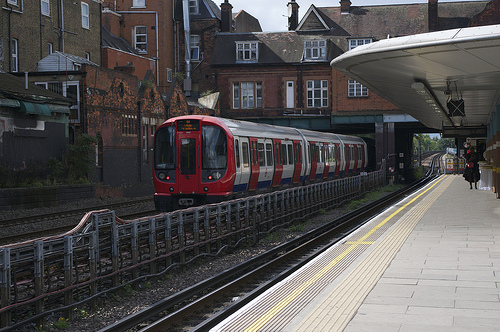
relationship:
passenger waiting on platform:
[460, 144, 480, 189] [209, 170, 499, 330]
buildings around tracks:
[3, 1, 485, 186] [18, 160, 428, 330]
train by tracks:
[141, 103, 393, 208] [217, 219, 319, 259]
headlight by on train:
[206, 172, 214, 182] [147, 109, 377, 214]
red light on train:
[207, 175, 212, 180] [147, 109, 377, 214]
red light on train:
[163, 172, 171, 181] [147, 109, 377, 214]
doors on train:
[235, 134, 370, 177] [229, 121, 354, 171]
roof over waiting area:
[326, 39, 478, 141] [370, 140, 489, 307]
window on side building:
[231, 83, 263, 106] [217, 21, 346, 137]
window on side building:
[306, 80, 328, 109] [217, 21, 346, 137]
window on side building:
[304, 40, 327, 60] [217, 21, 346, 137]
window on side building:
[305, 82, 332, 100] [211, 22, 341, 118]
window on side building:
[304, 42, 325, 59] [210, 2, 479, 125]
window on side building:
[188, 37, 203, 59] [176, 1, 216, 104]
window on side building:
[191, 0, 198, 11] [176, 1, 216, 104]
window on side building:
[128, 0, 146, 9] [176, 1, 216, 104]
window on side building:
[134, 25, 151, 49] [108, 0, 175, 89]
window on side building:
[67, 82, 79, 121] [108, 0, 175, 89]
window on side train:
[233, 134, 245, 169] [147, 109, 377, 214]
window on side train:
[240, 135, 264, 164] [148, 114, 371, 196]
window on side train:
[259, 138, 275, 157] [118, 100, 392, 189]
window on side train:
[235, 139, 241, 169] [147, 109, 377, 214]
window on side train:
[242, 142, 249, 168] [147, 109, 377, 214]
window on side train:
[258, 141, 265, 166] [147, 109, 377, 214]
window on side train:
[285, 141, 293, 163] [147, 109, 377, 214]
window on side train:
[198, 124, 226, 181] [147, 109, 377, 214]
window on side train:
[235, 137, 250, 177] [151, 101, 370, 218]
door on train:
[235, 136, 250, 186] [147, 109, 377, 214]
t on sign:
[446, 97, 464, 121] [446, 96, 466, 117]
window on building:
[306, 80, 328, 109] [206, 5, 497, 140]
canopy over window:
[20, 100, 53, 117] [33, 78, 54, 111]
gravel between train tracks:
[125, 262, 180, 297] [0, 158, 444, 326]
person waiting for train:
[465, 149, 481, 190] [147, 109, 377, 214]